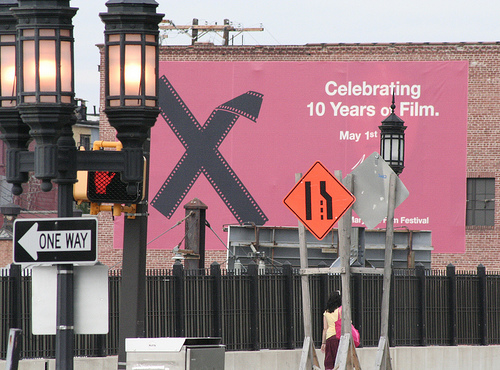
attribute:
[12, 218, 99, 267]
traffic sign — one way, white, black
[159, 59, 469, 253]
sign — painted, huge, brick, pink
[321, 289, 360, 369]
woman — standing, walking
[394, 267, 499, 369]
sidewalk — black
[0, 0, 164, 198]
street lights — huge, lit, older style, large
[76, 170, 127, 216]
crosswalk light — lit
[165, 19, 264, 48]
lines — power lines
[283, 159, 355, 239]
sign — orange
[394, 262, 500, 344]
fence — metal, iron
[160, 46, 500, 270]
building — brick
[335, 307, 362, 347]
purse — pink, oversized, large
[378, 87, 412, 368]
street light — tall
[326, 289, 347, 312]
her hair — dark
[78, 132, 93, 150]
windows — tinted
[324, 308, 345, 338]
shirt — yellow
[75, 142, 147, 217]
pedestrian sign — yellow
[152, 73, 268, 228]
painted x — large